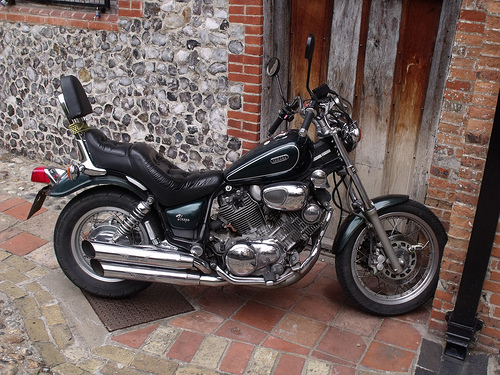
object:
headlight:
[352, 128, 360, 142]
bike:
[23, 32, 446, 315]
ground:
[293, 292, 322, 310]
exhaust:
[82, 241, 215, 287]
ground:
[0, 352, 212, 373]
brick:
[314, 322, 371, 364]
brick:
[220, 340, 255, 375]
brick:
[169, 330, 205, 360]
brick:
[291, 291, 343, 325]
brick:
[0, 197, 25, 213]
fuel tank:
[222, 136, 314, 183]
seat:
[82, 129, 221, 204]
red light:
[31, 167, 56, 184]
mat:
[80, 289, 194, 331]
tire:
[51, 184, 164, 301]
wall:
[84, 35, 230, 127]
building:
[0, 0, 480, 252]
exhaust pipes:
[81, 239, 200, 273]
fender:
[329, 192, 412, 255]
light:
[30, 166, 49, 183]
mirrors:
[264, 58, 281, 78]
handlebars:
[299, 100, 320, 139]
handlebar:
[265, 108, 286, 137]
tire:
[334, 198, 447, 316]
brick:
[449, 65, 471, 78]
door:
[279, 0, 446, 252]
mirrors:
[304, 37, 312, 59]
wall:
[445, 4, 499, 351]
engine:
[212, 192, 322, 276]